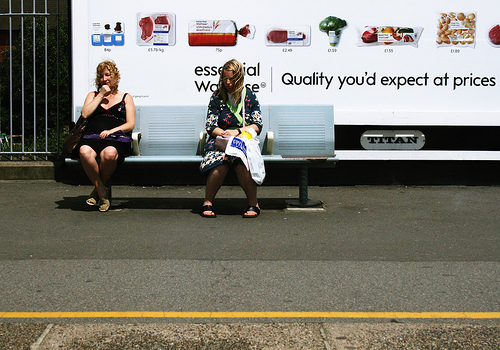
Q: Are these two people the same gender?
A: Yes, all the people are female.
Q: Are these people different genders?
A: No, all the people are female.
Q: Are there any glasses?
A: No, there are no glasses.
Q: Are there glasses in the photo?
A: No, there are no glasses.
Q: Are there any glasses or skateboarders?
A: No, there are no glasses or skateboarders.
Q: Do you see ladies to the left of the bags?
A: Yes, there is a lady to the left of the bags.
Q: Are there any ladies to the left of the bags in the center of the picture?
A: Yes, there is a lady to the left of the bags.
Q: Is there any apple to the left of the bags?
A: No, there is a lady to the left of the bags.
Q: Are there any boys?
A: No, there are no boys.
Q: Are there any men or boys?
A: No, there are no boys or men.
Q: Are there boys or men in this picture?
A: No, there are no boys or men.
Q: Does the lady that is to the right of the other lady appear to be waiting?
A: Yes, the lady is waiting.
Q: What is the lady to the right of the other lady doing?
A: The lady is waiting.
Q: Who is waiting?
A: The lady is waiting.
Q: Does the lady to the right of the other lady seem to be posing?
A: No, the lady is waiting.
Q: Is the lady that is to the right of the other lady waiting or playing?
A: The lady is waiting.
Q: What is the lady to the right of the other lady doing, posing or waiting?
A: The lady is waiting.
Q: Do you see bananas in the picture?
A: No, there are no bananas.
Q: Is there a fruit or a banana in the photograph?
A: No, there are no bananas or fruits.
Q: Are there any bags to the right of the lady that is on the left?
A: Yes, there are bags to the right of the lady.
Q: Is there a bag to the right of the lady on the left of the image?
A: Yes, there are bags to the right of the lady.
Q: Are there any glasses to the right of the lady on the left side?
A: No, there are bags to the right of the lady.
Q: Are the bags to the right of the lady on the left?
A: Yes, the bags are to the right of the lady.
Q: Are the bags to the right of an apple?
A: No, the bags are to the right of the lady.